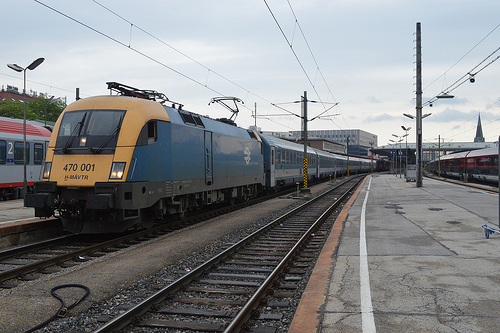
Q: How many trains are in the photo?
A: 1.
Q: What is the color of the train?
A: Yellow and black.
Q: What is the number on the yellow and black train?
A: 470 001.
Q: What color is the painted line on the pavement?
A: White.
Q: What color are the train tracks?
A: Black.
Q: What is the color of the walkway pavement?
A: Gray.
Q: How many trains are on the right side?
A: 1.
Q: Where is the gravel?
A: Under the train tracks.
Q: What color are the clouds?
A: Grayish.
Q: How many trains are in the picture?
A: Three.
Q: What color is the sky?
A: Blue.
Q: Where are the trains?
A: On the tracks.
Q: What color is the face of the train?
A: Yellow.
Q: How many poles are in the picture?
A: Three.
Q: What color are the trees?
A: Green.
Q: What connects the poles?
A: Wires.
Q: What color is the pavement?
A: Grey.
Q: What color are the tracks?
A: Black.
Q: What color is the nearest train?
A: Yellow and blue.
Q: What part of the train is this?
A: Wheels.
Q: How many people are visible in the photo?
A: None.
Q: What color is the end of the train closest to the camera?
A: Yellow.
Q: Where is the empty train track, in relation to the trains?
A: To the right.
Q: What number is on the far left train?
A: 2.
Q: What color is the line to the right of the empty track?
A: White.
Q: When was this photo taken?
A: Daytime.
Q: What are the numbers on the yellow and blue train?
A: 470 001.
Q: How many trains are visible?
A: Three.